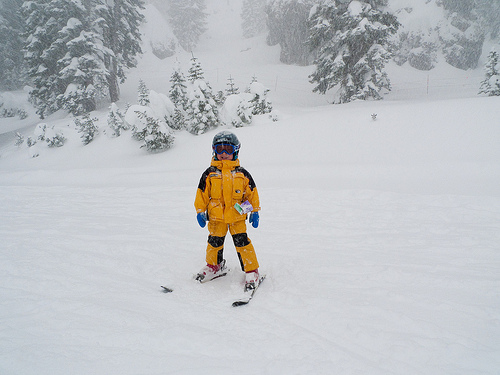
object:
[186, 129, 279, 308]
boy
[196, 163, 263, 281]
orange jacket/pants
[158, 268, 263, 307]
boy's skis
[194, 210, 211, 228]
boy's gloves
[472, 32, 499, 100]
trees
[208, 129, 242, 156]
helmet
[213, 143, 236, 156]
blue goggles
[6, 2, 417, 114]
small trees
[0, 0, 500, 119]
evergreen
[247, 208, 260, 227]
blue mitten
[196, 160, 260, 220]
jacket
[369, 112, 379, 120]
object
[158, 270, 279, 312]
skis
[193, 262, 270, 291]
shoes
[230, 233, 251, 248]
knee pads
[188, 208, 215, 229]
hand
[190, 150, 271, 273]
snow suit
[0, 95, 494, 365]
field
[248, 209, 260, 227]
mitten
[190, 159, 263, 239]
coat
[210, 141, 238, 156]
ski goggles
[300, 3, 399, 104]
tree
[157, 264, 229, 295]
skis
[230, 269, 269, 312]
skis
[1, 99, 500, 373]
snow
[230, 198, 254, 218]
ticket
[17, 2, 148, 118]
trees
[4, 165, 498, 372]
tracks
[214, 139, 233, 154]
lenses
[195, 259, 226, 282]
boots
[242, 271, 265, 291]
boots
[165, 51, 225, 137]
saplings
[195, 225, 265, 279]
pants